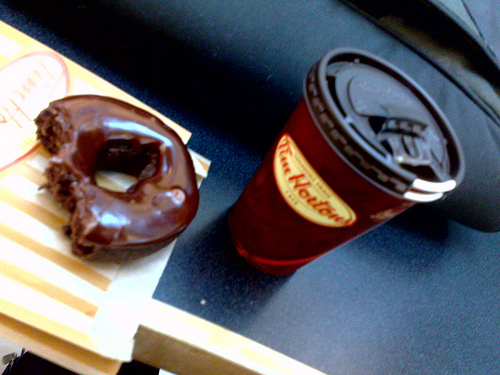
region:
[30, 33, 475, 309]
A chocolate donut with chocolate glaze and a coffee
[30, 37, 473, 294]
A chocolate donut with chocolate glaze and a coffee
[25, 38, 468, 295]
A chocolate donut with chocolate glaze and a coffee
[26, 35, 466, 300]
A chocolate donut with chocolate glaze and a coffee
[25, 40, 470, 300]
A chocolate donut with chocolate glaze and a coffee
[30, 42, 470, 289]
A chocolate donut with chocolate glaze and a coffee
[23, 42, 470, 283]
A chocolate donut with chocolate glaze and a coffee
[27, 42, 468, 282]
A chocolate donut with chocolate glaze and a coffee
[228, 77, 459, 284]
coffee cup on the table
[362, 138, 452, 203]
opening of lid is opened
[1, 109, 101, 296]
bitten chocolate donut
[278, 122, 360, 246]
name of coffee shop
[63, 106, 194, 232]
chocolate glaze on doughnut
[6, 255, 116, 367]
striped bag from cafe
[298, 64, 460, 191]
lid of coffee is black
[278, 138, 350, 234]
writing in the front is red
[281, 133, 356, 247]
label in front is oval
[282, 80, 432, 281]
a coffe botle ona stand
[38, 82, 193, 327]
the cake is put in a paper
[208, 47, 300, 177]
the floor is smooth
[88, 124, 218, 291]
the cake is brown in color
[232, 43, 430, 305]
the bottle is brown incolor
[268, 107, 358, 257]
the tin has a yellow label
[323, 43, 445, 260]
the tin lid is black in color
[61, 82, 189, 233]
the cake is made of chocolte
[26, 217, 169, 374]
the papers are lightbrown incolor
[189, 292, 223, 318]
tiny white spot on table top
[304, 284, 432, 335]
blue color on surface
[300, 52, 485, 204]
black lid on coffee cup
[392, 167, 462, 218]
white part of the coffee lid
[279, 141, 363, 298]
tall red coffee cup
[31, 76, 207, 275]
half eaten chocolate donut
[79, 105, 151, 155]
chocolate frosting on donut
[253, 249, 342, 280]
red swirl on coffee cup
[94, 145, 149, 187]
hole in chocolate donut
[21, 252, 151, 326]
brown and tan paper bag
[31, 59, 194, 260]
pastry on the table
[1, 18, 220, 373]
bag on the table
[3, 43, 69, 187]
graphic on the bag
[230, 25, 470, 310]
container on the table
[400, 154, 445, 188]
opening in lid of container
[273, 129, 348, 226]
branding on the container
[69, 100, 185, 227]
frosting on the pastry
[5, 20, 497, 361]
table with item on it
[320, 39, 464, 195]
top to the container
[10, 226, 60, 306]
stripes on the bag